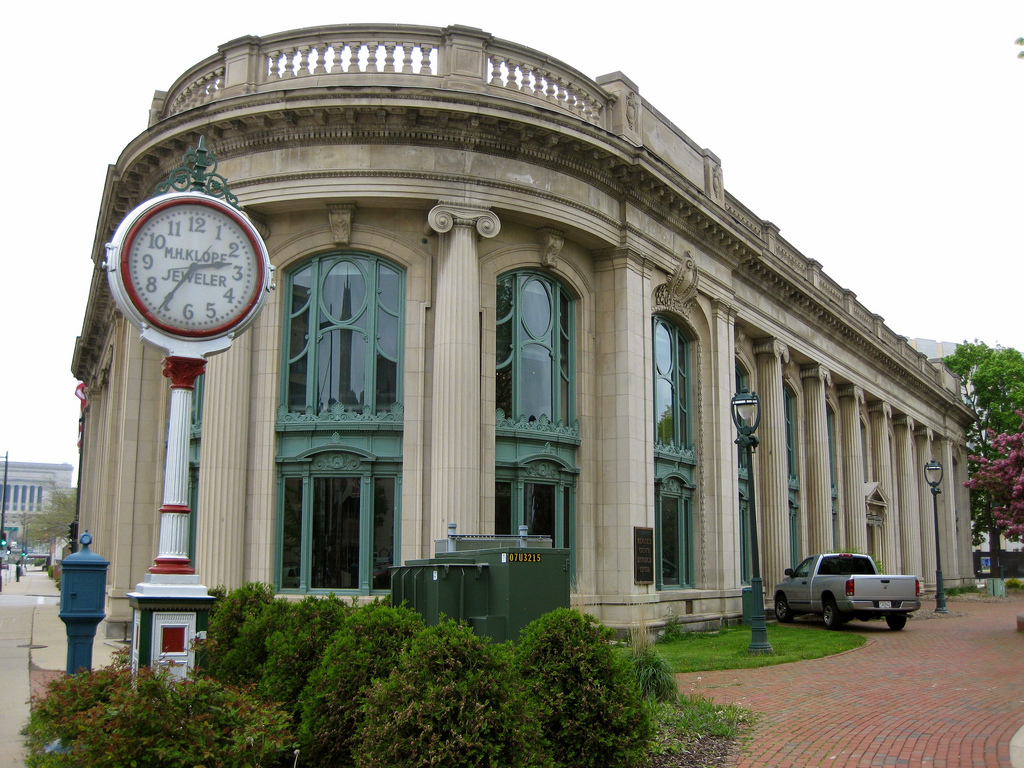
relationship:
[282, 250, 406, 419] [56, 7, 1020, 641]
window on building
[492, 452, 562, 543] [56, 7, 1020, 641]
window on building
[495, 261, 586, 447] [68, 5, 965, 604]
window on building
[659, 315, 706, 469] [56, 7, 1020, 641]
window on building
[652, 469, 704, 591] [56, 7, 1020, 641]
window on building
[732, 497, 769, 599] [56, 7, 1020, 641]
window on building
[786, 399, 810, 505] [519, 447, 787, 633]
window on building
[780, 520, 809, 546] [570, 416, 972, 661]
window on building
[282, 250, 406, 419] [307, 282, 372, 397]
window with greenmetal frame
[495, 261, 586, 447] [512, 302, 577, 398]
window with greenmetal frame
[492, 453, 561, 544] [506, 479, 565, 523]
window with greenmetal frame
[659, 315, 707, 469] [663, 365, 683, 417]
window with greenmetal frame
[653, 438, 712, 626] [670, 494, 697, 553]
window with greenmetal frame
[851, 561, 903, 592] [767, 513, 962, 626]
grey pickup truck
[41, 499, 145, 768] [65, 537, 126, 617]
post with a decorative top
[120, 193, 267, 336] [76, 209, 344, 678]
clock on a pole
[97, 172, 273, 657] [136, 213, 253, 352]
standing red and white clock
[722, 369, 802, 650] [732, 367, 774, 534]
green street light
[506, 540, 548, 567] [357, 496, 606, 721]
yellow number on side of green metal box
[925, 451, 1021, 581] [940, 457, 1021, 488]
lavender tree flowers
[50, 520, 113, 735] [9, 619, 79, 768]
pole on sidewalk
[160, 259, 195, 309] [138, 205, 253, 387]
black time arrows in clock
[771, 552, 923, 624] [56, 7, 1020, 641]
truck parked near building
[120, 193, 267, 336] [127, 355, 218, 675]
clock on pole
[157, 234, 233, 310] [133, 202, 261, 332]
hands on clock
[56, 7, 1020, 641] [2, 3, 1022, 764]
building in city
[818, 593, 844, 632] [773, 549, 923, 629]
wheel on truck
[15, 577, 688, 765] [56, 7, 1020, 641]
shrubs in front of building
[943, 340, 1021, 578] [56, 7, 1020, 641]
trees beside building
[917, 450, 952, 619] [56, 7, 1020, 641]
street light beside building